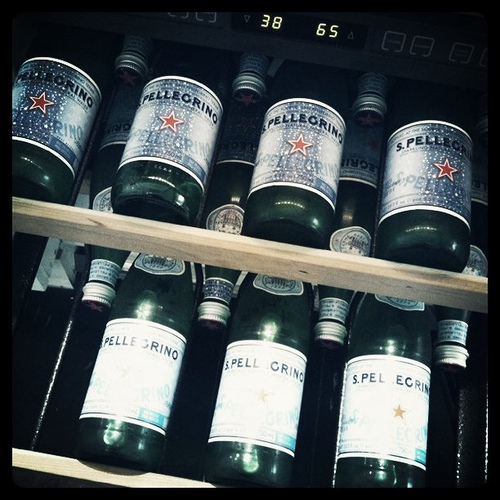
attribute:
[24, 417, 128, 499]
shelf — wood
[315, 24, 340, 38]
number — 65, green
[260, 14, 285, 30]
number — 38, green, here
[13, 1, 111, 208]
bottle — green, wine, in refrigerator, on shelf, 750ml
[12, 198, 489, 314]
shelf — top, wooden, wood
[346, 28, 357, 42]
arrow — pointing, up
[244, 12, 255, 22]
arrow — pointing, down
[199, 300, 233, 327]
lid — aluminum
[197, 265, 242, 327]
bottle — upside down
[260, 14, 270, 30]
number — green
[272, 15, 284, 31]
number — green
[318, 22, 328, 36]
six — green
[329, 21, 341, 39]
five — green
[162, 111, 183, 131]
star — gold, red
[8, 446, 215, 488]
rack — bottom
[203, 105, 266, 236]
water — s pellegrino